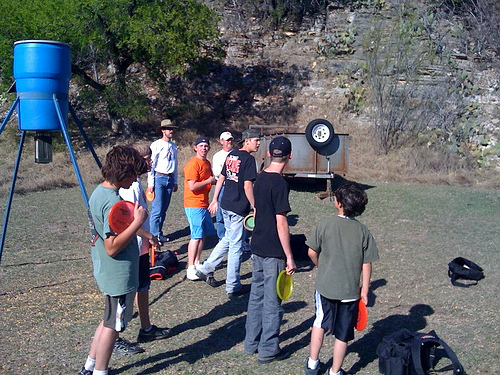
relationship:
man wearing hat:
[146, 118, 180, 243] [156, 116, 179, 130]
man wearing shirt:
[180, 136, 215, 277] [182, 157, 213, 207]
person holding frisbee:
[78, 144, 162, 374] [109, 200, 137, 238]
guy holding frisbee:
[243, 137, 299, 362] [277, 268, 293, 301]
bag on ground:
[148, 249, 180, 281] [0, 151, 497, 374]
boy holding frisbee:
[304, 182, 383, 374] [356, 297, 367, 331]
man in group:
[146, 118, 180, 243] [82, 118, 380, 372]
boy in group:
[304, 182, 383, 374] [82, 118, 380, 372]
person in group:
[78, 144, 162, 374] [82, 118, 380, 372]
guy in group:
[243, 137, 299, 362] [82, 118, 380, 372]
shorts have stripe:
[311, 292, 357, 340] [313, 292, 325, 331]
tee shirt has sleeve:
[251, 171, 291, 261] [270, 175, 291, 216]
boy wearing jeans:
[201, 126, 262, 298] [199, 209, 248, 291]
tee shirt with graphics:
[221, 149, 256, 219] [222, 152, 245, 184]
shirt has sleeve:
[182, 157, 213, 207] [185, 158, 200, 182]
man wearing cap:
[180, 136, 215, 277] [191, 135, 210, 146]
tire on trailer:
[305, 118, 336, 148] [248, 120, 349, 198]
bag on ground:
[446, 257, 484, 287] [0, 151, 497, 374]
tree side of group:
[0, 1, 231, 135] [82, 118, 380, 372]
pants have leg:
[240, 256, 288, 358] [244, 255, 263, 352]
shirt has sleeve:
[251, 171, 291, 261] [270, 175, 291, 216]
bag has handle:
[373, 326, 466, 374] [410, 328, 463, 374]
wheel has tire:
[312, 127, 326, 139] [305, 118, 336, 148]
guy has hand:
[243, 137, 299, 362] [284, 259, 299, 274]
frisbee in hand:
[277, 268, 293, 301] [284, 259, 299, 274]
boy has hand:
[304, 182, 383, 374] [359, 289, 370, 305]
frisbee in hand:
[356, 297, 367, 331] [359, 289, 370, 305]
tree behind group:
[0, 1, 231, 135] [82, 118, 380, 372]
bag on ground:
[373, 326, 466, 374] [0, 151, 497, 374]